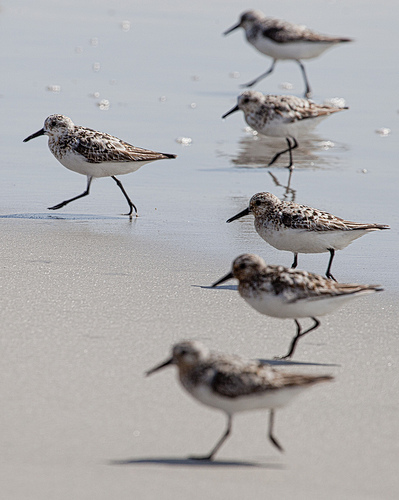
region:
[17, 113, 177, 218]
Sandpiper running on sand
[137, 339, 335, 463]
Blurry sandpiper on the sand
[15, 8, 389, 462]
Group of sandpipers running across the sand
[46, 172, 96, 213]
Bent leg on sandpiper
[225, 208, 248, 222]
Long black beak on bird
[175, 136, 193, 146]
Bubble in water near birds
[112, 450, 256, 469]
Shadow of bird on sand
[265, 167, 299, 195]
Reflection of sandpiper legs in water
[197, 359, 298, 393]
Brown and tan wing on bird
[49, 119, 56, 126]
Small black eye on bird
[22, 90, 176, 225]
bird standing in the stand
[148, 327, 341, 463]
bird standing in the sand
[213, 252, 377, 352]
birds standing in the stand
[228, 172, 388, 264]
bird standing in the sand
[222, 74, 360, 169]
bird standing in the sand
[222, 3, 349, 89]
bird standing in the sand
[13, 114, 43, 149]
beak on the bird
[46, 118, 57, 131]
eye on the bird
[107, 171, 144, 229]
leg on the bird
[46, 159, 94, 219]
leg on the bird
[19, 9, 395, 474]
several sandpiper birds on the sand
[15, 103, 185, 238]
a sandpiper bird on the sea sand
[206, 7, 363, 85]
a sandpiper bird on the sea sand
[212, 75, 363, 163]
a sandpiper bird on the sea sand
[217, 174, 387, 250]
a sandpiper bird on the sea sand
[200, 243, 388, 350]
a sandpiper bird on the sea sand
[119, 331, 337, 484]
a sandpiper bird on the sea sand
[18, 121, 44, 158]
the bill of a bird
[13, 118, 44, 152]
the beak of a bird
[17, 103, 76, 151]
the head of a bird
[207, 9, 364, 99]
The bird is on the ground.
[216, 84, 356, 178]
The bird is on the ground.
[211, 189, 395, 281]
The bird is on the ground.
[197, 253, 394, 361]
The bird is on the ground.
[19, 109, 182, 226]
The bird is on the ground.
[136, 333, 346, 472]
The bird is feathered.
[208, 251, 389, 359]
The bird is feathered.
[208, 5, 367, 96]
The bird is feathered.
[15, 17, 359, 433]
sandpipers walking along the beach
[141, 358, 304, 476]
a slightly blurry bird on one foot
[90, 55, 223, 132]
some shells washed up on shore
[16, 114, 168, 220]
a young snowy plover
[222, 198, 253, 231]
the beak of a shore dwelling bird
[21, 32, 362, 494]
a group of 6 birds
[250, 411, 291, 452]
a birds foot off the ground